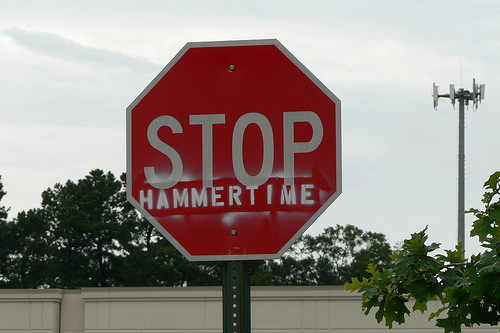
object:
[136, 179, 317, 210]
writing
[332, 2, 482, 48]
blue sky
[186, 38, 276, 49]
border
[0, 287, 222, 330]
fence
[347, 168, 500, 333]
plant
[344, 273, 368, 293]
leaf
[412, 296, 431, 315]
leaf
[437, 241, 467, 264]
leaf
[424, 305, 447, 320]
leaf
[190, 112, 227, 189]
letter t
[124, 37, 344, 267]
sign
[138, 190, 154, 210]
white letter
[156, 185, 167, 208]
white letter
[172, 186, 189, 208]
white letter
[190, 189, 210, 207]
white letter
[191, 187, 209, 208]
letter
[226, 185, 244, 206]
letter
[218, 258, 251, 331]
pole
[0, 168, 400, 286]
trees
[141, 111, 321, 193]
word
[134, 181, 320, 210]
paint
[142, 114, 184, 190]
letter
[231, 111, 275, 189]
letter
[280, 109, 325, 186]
letter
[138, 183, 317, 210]
graffiti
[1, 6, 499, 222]
clouds